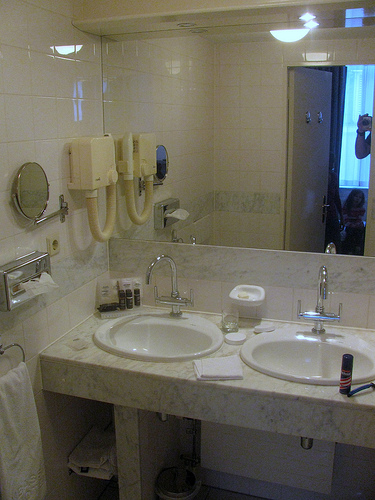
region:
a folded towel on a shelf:
[52, 420, 124, 497]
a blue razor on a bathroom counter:
[347, 377, 373, 402]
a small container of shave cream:
[331, 341, 366, 395]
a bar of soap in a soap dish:
[224, 280, 262, 304]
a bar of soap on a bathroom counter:
[217, 329, 246, 347]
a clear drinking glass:
[213, 303, 239, 336]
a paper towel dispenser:
[0, 253, 57, 303]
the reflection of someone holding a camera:
[358, 99, 373, 154]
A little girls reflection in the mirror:
[338, 188, 369, 250]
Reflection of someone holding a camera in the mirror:
[354, 111, 372, 161]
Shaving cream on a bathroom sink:
[339, 348, 355, 398]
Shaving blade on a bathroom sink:
[346, 378, 373, 396]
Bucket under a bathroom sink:
[150, 463, 205, 498]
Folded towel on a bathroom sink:
[191, 354, 248, 384]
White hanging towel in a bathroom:
[0, 341, 46, 498]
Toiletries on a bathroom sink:
[98, 278, 148, 314]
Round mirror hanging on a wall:
[4, 152, 55, 229]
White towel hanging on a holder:
[0, 342, 51, 498]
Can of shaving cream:
[336, 351, 353, 395]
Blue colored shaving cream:
[347, 379, 374, 400]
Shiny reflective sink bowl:
[91, 304, 229, 362]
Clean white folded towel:
[188, 350, 249, 384]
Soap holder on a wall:
[225, 280, 266, 312]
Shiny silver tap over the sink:
[293, 261, 346, 342]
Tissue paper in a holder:
[0, 251, 60, 313]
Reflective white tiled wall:
[1, 0, 106, 311]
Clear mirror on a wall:
[102, 35, 374, 260]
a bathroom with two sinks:
[6, 110, 330, 397]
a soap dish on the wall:
[208, 276, 273, 321]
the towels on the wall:
[5, 251, 65, 306]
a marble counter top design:
[70, 352, 266, 420]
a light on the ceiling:
[256, 7, 326, 62]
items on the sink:
[339, 347, 374, 400]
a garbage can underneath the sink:
[141, 439, 207, 499]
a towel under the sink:
[48, 415, 127, 477]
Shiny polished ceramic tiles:
[4, 24, 105, 340]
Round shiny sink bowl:
[103, 308, 232, 363]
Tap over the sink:
[293, 263, 344, 338]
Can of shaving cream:
[332, 351, 357, 400]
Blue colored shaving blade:
[347, 378, 373, 398]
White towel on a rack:
[0, 343, 53, 499]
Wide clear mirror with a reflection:
[99, 36, 374, 262]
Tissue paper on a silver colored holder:
[0, 249, 62, 313]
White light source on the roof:
[256, 18, 318, 50]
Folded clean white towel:
[189, 350, 250, 383]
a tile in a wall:
[5, 3, 33, 53]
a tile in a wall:
[26, 1, 56, 62]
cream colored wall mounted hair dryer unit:
[64, 132, 117, 243]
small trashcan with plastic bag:
[152, 461, 202, 498]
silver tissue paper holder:
[1, 250, 59, 312]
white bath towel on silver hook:
[0, 340, 49, 498]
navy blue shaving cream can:
[337, 353, 355, 394]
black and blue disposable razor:
[346, 381, 374, 399]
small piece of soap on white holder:
[227, 282, 265, 308]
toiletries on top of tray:
[96, 276, 143, 318]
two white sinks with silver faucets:
[91, 250, 374, 385]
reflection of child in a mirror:
[340, 186, 367, 255]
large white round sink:
[91, 311, 223, 364]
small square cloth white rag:
[191, 352, 246, 382]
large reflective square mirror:
[102, 15, 374, 259]